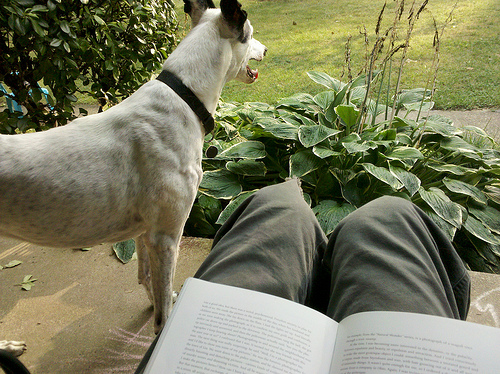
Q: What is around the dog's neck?
A: Collar.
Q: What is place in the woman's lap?
A: An open book.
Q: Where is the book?
A: Top of woman's legs.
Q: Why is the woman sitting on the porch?
A: To read a novel.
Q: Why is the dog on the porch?
A: Fresh air.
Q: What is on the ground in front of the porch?
A: A green plant.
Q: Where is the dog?
A: Standing on a porch.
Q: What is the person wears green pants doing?
A: Reading book.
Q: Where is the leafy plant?
A: Setting on concrete.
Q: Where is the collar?
A: Around dog's neck.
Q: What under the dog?
A: Purple lines.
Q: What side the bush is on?
A: Left side.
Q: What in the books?
A: Small writings.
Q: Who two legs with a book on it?
A: The person.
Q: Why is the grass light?
A: Sun shining.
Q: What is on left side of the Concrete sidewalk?
A: Green grass.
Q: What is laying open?
A: The book.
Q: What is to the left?
A: A tall green bush.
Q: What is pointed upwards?
A: The dogs ears.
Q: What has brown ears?
A: A white dog.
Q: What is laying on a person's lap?
A: An open book.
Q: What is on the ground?
A: Green plants.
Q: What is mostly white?
A: A dog.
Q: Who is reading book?
A: A person.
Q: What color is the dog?
A: The dog is white.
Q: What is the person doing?
A: The person is reading a book.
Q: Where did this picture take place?
A: It took place outside probably on the porch.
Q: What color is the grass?
A: The grass is green.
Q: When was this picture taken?
A: It was taken in the day time.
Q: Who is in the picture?
A: A dog and a person is in the picture.